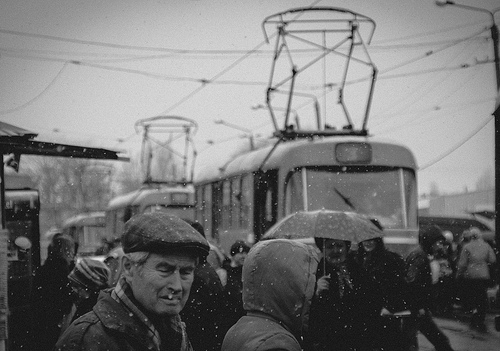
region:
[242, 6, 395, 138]
electric lines over train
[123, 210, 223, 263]
golf cap on old man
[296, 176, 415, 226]
glass windshield of train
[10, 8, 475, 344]
snow falling over station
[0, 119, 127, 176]
awning of train station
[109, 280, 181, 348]
plaid scarf on man's neck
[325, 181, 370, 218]
windshield wiper on train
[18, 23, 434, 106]
electric lines crossing tracks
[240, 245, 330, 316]
hoodie over person on platform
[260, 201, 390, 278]
open umbrella in hand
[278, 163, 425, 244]
Large window on a bus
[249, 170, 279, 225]
Large window on a bus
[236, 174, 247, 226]
Large window on a bus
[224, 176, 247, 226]
Large window on a bus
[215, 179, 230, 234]
Large window on a bus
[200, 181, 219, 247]
Large window on a bus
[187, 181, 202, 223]
Large window on a bus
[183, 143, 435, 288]
Large black bus on the pavement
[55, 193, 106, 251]
Large black bus on the pavement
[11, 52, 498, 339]
snow falling in outdoor scene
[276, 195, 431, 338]
older woman holding an umbrella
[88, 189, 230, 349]
gentleman wearing a plaid beret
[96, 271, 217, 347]
gentleman wearing a plaid scarf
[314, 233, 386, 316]
woman wearing scarf around neck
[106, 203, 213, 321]
gentleman has his eyes closed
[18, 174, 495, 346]
people waiting for trolley cars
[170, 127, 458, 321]
trolley cars moving along line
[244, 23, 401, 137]
top of trolley car connecting to wires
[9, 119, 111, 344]
station where passengers wait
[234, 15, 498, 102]
ELECTRIC LINES OVER TRAMS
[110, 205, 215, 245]
GOLFER HAT ON MAN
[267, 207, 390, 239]
OPEN UMBRELLA NEAR TRAIN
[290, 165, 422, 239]
GLASS WINDSHIELD OF TRAIN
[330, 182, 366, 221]
WINDSHIELD WIPER ON TRAIN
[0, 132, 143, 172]
AWNING OF STATION ON LEFT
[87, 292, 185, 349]
PLAID SCARF ON MAN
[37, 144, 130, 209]
TALL TREES IN BACKGROUND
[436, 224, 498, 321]
PEOPLE ON RIGHT OF TRAIN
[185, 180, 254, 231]
ROW OF WINDOWS ON TRAM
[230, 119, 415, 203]
old light rail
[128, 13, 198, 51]
white clouds in blue sky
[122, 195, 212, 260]
hat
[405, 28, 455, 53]
white clouds in blue sky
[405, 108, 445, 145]
white clouds in blue sky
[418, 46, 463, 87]
white clouds in blue sky